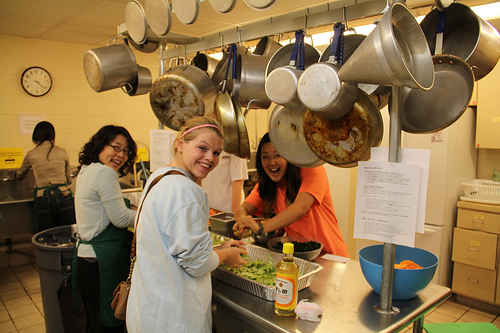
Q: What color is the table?
A: Silver.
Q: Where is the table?
A: In the middle of the room.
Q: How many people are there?
A: Four.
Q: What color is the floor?
A: White.